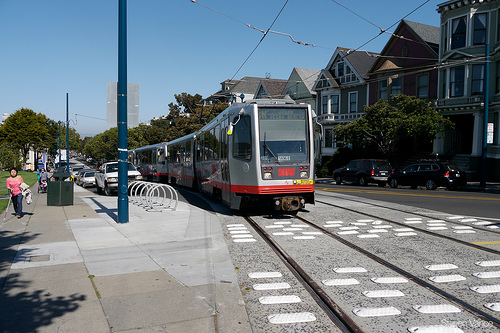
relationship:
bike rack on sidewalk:
[122, 174, 184, 220] [17, 210, 231, 325]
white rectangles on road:
[228, 202, 466, 327] [223, 196, 484, 330]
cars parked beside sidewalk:
[74, 167, 141, 187] [25, 185, 245, 330]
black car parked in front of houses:
[387, 163, 468, 190] [308, 0, 496, 185]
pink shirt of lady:
[1, 174, 35, 202] [6, 168, 24, 219]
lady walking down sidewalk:
[6, 168, 24, 219] [12, 188, 239, 325]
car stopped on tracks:
[127, 98, 316, 216] [242, 207, 469, 327]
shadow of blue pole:
[88, 200, 118, 219] [118, 3, 129, 223]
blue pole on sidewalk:
[118, 3, 129, 223] [12, 188, 239, 325]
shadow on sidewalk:
[88, 200, 118, 219] [12, 188, 239, 325]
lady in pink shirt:
[6, 168, 24, 219] [6, 175, 25, 194]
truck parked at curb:
[95, 161, 145, 195] [58, 161, 119, 199]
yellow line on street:
[310, 182, 498, 207] [315, 172, 497, 252]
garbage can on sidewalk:
[42, 167, 76, 207] [22, 180, 231, 324]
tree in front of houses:
[333, 90, 455, 160] [300, 6, 498, 163]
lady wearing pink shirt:
[0, 164, 31, 215] [4, 177, 24, 196]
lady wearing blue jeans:
[6, 168, 24, 219] [10, 191, 26, 213]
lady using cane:
[6, 168, 24, 219] [3, 196, 11, 221]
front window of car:
[256, 104, 312, 184] [127, 98, 316, 216]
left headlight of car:
[261, 170, 274, 183] [127, 98, 316, 216]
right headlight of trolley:
[298, 170, 312, 180] [115, 89, 318, 220]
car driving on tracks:
[127, 98, 316, 216] [250, 184, 490, 329]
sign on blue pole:
[109, 82, 143, 120] [109, 3, 134, 223]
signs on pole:
[29, 161, 58, 190] [469, 112, 493, 149]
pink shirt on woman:
[6, 175, 23, 197] [4, 170, 54, 234]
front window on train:
[259, 107, 309, 164] [162, 101, 343, 233]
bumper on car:
[232, 171, 319, 211] [158, 100, 355, 239]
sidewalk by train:
[40, 200, 220, 324] [97, 104, 300, 207]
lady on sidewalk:
[6, 168, 24, 219] [24, 208, 199, 330]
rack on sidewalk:
[126, 171, 199, 215] [47, 180, 275, 322]